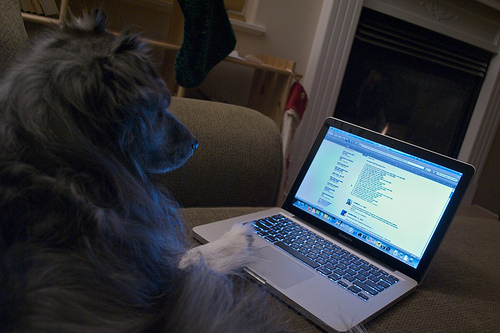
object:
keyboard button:
[362, 263, 372, 273]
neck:
[8, 132, 145, 207]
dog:
[0, 11, 370, 332]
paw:
[175, 225, 258, 280]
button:
[278, 218, 288, 224]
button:
[276, 212, 287, 218]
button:
[283, 217, 292, 224]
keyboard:
[236, 212, 401, 302]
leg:
[177, 224, 255, 299]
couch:
[0, 0, 288, 207]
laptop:
[190, 116, 479, 332]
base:
[190, 207, 420, 332]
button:
[295, 233, 307, 242]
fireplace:
[310, 6, 499, 203]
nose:
[183, 131, 199, 150]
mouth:
[151, 138, 200, 177]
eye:
[144, 98, 162, 111]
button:
[348, 281, 358, 293]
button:
[354, 280, 378, 295]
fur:
[44, 211, 156, 295]